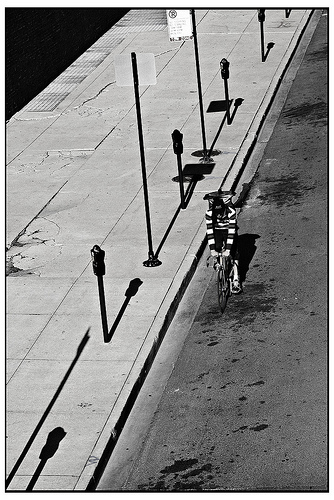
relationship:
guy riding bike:
[202, 186, 245, 296] [206, 253, 231, 312]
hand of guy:
[208, 249, 220, 259] [202, 186, 245, 296]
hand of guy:
[219, 248, 231, 259] [202, 186, 245, 296]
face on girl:
[214, 205, 221, 217] [205, 199, 239, 286]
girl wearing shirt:
[204, 188, 250, 298] [204, 207, 238, 258]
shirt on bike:
[202, 207, 234, 256] [204, 244, 235, 312]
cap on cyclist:
[208, 196, 228, 212] [201, 195, 246, 308]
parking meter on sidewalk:
[91, 244, 110, 341] [6, 8, 314, 489]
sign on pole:
[166, 8, 194, 41] [190, 9, 218, 156]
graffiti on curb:
[78, 449, 105, 468] [103, 314, 159, 436]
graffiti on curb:
[78, 449, 105, 468] [246, 64, 281, 144]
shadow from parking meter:
[109, 275, 143, 338] [90, 243, 111, 342]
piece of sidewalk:
[25, 146, 94, 160] [6, 8, 314, 489]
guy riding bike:
[204, 199, 241, 293] [205, 253, 242, 312]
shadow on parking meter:
[111, 275, 142, 337] [87, 243, 113, 340]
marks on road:
[259, 82, 317, 133] [122, 49, 330, 449]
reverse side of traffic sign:
[111, 51, 157, 87] [104, 44, 165, 96]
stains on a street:
[162, 434, 231, 498] [89, 62, 322, 496]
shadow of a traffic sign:
[23, 422, 67, 495] [112, 44, 163, 269]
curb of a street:
[86, 10, 314, 490] [93, 20, 326, 490]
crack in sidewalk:
[14, 76, 121, 122] [6, 8, 314, 489]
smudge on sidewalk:
[225, 165, 258, 221] [54, 230, 72, 326]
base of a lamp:
[142, 246, 160, 266] [118, 52, 158, 104]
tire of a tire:
[214, 268, 226, 315] [216, 268, 228, 312]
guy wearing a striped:
[202, 186, 245, 296] [205, 217, 235, 247]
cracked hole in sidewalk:
[4, 212, 63, 278] [6, 8, 314, 489]